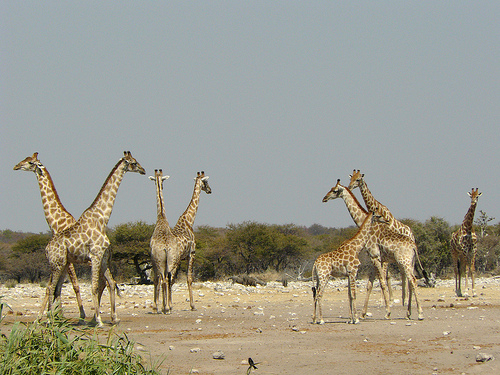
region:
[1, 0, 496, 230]
a sky with no clouds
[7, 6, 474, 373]
a scene outside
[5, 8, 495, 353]
a scene of a field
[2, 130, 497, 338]
a group of giraffes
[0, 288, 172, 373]
a patch of grass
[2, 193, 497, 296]
a row of trees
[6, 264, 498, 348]
a row of rocks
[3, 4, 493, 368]
a place where animals are walking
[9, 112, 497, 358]
these are animals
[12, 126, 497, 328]
beuatful creatures roaming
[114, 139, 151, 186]
head of the giraffe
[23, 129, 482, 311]
many giraffes on the ground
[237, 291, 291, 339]
rocks on the ground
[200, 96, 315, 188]
blue sky above the land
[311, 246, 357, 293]
brown spots on giraffe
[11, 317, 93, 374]
green bush on ground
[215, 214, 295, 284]
trees behind the giraffes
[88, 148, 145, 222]
long neck of the giraffe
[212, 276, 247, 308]
silver rocks on ground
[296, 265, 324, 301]
tail of the giraffe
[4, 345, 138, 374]
WILD GREEN FOLIAGE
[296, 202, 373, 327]
YOUNG WILD GIRAFFE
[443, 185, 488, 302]
GIRAFFE WALKING TOWARDS CAMERA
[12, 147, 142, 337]
TWO GIRAFFE HEADS, ONE BODY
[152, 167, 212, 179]
FOUR GIRAFFE HORNS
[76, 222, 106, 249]
BROWN AND WHITE HAIR ON GIRAFFE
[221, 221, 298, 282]
GREEN TREES IN THE DISTANCE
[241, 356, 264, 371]
BLACK BIRD ON A SMALL BRANCH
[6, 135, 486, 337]
HERD OF EIGHT GIRAFFES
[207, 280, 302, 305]
WHITE ROCKY AREA NEAR TREE AREA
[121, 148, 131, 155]
horns on a giraffe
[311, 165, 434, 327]
three giraffes in a rocky field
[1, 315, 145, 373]
shrubs in the foreground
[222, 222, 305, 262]
leaves of the trees in the background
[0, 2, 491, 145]
gray overcast sky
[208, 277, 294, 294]
rocks laying in a field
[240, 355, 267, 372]
bird perched on the ground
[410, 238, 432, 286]
tail of a giraffe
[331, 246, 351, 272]
spots on a giraffe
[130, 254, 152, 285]
trunk of the tree in the background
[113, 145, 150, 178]
the head of a giraffe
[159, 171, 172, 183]
the ear of a giraffe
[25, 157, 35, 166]
the eye of a giraffe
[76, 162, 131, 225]
the neck of a giraffe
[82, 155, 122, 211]
the mane of a giraffe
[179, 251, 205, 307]
the leg of a giraffe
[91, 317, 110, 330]
the hoof of a giraffe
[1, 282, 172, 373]
a green leafy plant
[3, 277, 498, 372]
a brown sandy beach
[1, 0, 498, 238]
a gray sky